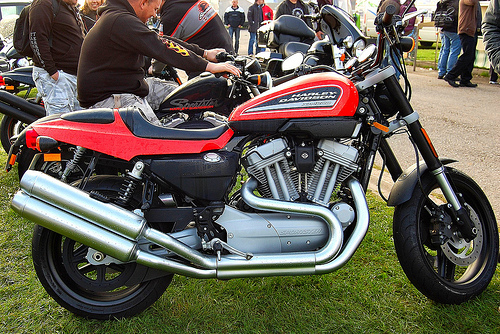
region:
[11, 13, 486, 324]
this is a bike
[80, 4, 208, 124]
this is a person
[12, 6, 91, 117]
this is a person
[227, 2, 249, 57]
this is a person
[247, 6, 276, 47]
this is a person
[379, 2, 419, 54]
this is a person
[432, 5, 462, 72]
this is a person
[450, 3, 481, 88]
this is a person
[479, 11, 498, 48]
this is a person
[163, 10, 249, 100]
this is a person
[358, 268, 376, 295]
part of a grpound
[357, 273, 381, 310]
part of a grass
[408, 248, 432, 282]
edge of a wheel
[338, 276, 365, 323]
part of a ground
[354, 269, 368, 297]
part of a grass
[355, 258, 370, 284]
part of a grass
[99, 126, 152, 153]
the motorcycle is red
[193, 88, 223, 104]
the motorcycle is black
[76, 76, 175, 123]
he is sitting onn the bike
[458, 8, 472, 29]
the jacket is brown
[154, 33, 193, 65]
the sleeve has a flame logo on it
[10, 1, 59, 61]
the person is carring a backpack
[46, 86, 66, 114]
the pants are white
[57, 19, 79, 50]
the shirt is brown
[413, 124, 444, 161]
the light is orange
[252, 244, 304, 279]
the pipe is silver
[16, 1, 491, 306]
the bike is parked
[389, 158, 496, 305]
the wheels are black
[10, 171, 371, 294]
the pipes are silver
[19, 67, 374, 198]
the bike is red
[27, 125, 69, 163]
the signal light on the back side of the bike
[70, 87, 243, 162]
the seat is black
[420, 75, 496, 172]
the road is light brownish grey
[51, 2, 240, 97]
man sitting on a bike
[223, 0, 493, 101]
people standing in the street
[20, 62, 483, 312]
the bike is on the grass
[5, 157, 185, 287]
the exhaust is silver in colour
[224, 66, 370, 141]
the tank is red in colour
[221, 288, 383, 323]
the grass is green in colour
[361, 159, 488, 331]
the tyre is made of a tube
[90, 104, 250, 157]
the seat is black in colour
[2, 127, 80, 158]
the light is red in colour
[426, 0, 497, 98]
peole are walking on the road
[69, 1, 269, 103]
people are on the bikes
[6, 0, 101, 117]
the man has a backpack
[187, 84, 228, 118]
the bike is black in color